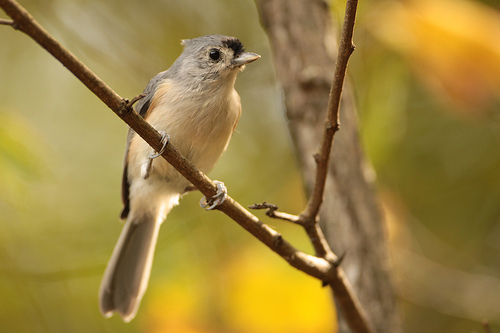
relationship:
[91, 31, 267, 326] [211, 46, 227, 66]
bird has eye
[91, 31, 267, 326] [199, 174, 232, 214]
bird has claw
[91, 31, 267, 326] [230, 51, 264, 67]
bird has beak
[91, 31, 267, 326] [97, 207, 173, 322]
bird has tail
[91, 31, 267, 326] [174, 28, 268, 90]
bird has head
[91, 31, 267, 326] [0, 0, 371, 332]
bird on tree branch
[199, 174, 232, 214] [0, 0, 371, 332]
claw clutching tree branch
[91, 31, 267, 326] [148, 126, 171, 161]
bird has foot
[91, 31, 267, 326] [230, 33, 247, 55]
bird has spot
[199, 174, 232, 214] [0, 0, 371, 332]
claw gripping tree branch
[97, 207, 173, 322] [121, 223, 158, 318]
tail has feather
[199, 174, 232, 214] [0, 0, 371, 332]
claw attached to tree branch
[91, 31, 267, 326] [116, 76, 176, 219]
bird has wing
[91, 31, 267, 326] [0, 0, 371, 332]
bird sitting on tree branch